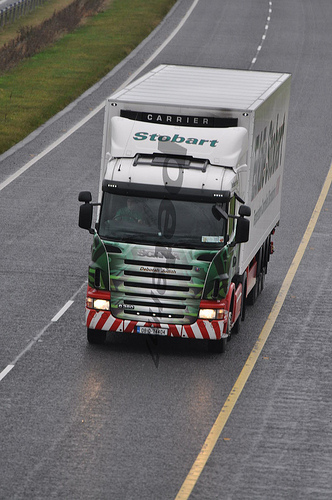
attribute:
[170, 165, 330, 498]
line — yellow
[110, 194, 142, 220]
man — one, driving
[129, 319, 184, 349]
license plate — white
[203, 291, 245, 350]
wheel — black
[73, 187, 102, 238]
mirror — black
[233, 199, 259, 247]
mirror — black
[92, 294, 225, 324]
light — yellow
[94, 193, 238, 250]
window — large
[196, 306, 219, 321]
headlight — on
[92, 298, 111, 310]
headlight — on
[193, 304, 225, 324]
light — white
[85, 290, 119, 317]
light — white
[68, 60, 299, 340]
truck — large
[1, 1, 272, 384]
lines — white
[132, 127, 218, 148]
print — green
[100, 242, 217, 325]
grill — colorful